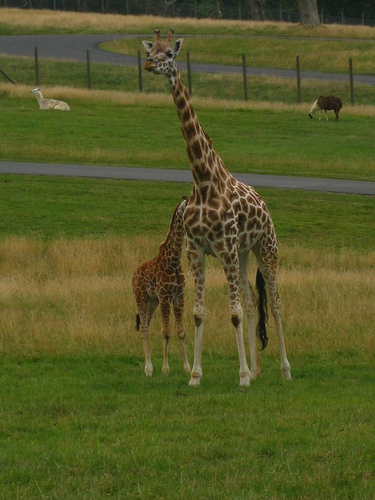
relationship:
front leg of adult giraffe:
[179, 228, 211, 387] [139, 23, 292, 389]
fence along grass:
[1, 47, 372, 104] [1, 171, 373, 495]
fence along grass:
[1, 47, 372, 104] [0, 52, 373, 181]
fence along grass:
[1, 47, 372, 104] [1, 6, 374, 72]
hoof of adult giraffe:
[228, 372, 252, 389] [139, 23, 292, 389]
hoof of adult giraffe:
[181, 360, 204, 388] [139, 23, 292, 389]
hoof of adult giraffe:
[276, 360, 297, 388] [139, 23, 292, 389]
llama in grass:
[27, 85, 72, 115] [3, 364, 315, 488]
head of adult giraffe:
[136, 22, 189, 80] [139, 23, 292, 389]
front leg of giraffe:
[210, 233, 251, 390] [114, 33, 343, 396]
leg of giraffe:
[252, 231, 318, 385] [126, 18, 316, 398]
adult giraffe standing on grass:
[139, 23, 292, 389] [1, 171, 373, 495]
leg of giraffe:
[164, 319, 225, 394] [119, 44, 304, 372]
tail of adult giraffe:
[253, 262, 269, 350] [139, 23, 292, 389]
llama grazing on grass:
[308, 94, 344, 123] [0, 52, 373, 181]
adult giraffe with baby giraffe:
[139, 23, 297, 390] [117, 193, 202, 378]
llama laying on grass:
[29, 87, 71, 112] [2, 95, 373, 180]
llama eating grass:
[304, 86, 349, 116] [0, 82, 373, 180]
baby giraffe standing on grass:
[130, 193, 193, 379] [68, 199, 101, 248]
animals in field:
[26, 26, 344, 384] [1, 4, 373, 498]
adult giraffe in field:
[139, 23, 292, 389] [2, 171, 374, 498]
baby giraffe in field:
[130, 193, 193, 379] [2, 171, 374, 498]